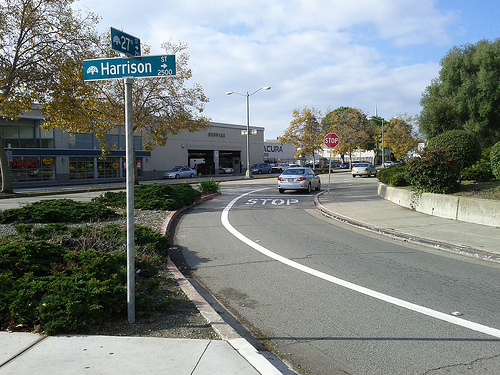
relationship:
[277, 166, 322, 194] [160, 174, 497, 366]
car on road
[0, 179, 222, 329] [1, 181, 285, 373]
shrubs in median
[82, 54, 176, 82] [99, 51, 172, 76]
green streetsign for harrison street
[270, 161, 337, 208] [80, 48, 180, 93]
car passing sign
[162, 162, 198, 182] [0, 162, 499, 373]
car on street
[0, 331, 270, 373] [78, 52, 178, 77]
sidewalk near street sign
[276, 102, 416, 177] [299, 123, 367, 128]
trees with yellow leaves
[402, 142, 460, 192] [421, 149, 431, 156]
bush with flowers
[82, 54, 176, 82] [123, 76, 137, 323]
green streetsign on pole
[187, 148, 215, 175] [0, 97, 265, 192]
bay on building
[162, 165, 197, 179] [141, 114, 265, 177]
car parked by automotive garage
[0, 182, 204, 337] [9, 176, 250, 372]
shrubs on corner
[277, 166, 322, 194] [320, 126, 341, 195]
car stopped at stop sign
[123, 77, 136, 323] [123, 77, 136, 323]
pole on pole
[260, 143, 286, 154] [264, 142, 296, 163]
word on acura building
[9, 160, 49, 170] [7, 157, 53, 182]
word on window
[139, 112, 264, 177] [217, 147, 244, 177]
automotive garage with bay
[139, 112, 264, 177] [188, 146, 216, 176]
automotive garage with bay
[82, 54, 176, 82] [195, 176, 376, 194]
green streetsign for intersection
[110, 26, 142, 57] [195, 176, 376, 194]
green streetsign for intersection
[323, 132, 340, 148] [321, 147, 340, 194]
sign on pole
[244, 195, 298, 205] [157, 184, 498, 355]
stop painted on road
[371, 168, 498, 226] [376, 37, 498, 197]
cement wal and landscaping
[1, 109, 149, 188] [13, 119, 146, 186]
storefront with window